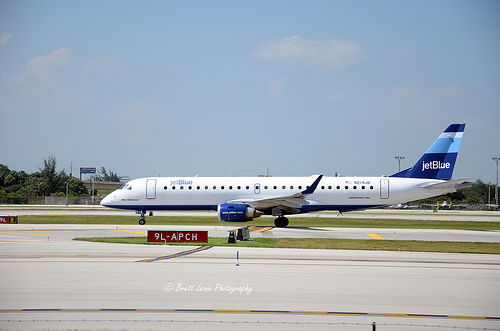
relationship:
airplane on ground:
[100, 123, 460, 221] [1, 229, 497, 328]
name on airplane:
[165, 181, 194, 186] [100, 123, 460, 221]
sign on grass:
[145, 230, 202, 243] [77, 232, 495, 258]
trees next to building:
[1, 165, 86, 203] [80, 175, 127, 194]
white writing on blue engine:
[223, 208, 245, 214] [218, 201, 256, 220]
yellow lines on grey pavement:
[354, 229, 392, 242] [117, 223, 495, 239]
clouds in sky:
[262, 32, 356, 60] [1, 3, 498, 177]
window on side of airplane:
[162, 185, 169, 190] [100, 123, 460, 221]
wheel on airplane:
[271, 217, 288, 226] [100, 123, 460, 221]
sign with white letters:
[145, 230, 202, 243] [153, 232, 203, 241]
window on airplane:
[370, 186, 376, 191] [100, 123, 460, 221]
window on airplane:
[361, 185, 367, 190] [100, 123, 460, 221]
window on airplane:
[351, 185, 356, 190] [100, 123, 460, 221]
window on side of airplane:
[344, 185, 349, 192] [100, 123, 460, 221]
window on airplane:
[336, 184, 341, 189] [100, 123, 460, 221]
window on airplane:
[320, 185, 328, 193] [100, 123, 460, 221]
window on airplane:
[328, 187, 332, 190] [100, 123, 460, 221]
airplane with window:
[100, 123, 460, 221] [299, 184, 305, 189]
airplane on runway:
[100, 123, 460, 221] [6, 216, 496, 264]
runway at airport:
[6, 216, 496, 264] [3, 4, 498, 329]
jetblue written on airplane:
[169, 178, 200, 186] [100, 123, 460, 221]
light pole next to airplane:
[484, 151, 500, 219] [100, 123, 460, 221]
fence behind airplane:
[28, 195, 106, 208] [100, 123, 460, 221]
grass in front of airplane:
[77, 232, 495, 258] [100, 123, 460, 221]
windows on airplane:
[160, 178, 391, 192] [100, 123, 460, 221]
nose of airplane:
[101, 186, 127, 213] [100, 123, 460, 221]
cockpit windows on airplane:
[118, 184, 134, 191] [100, 123, 460, 221]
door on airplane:
[145, 179, 158, 199] [100, 123, 460, 221]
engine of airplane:
[218, 201, 256, 220] [100, 123, 460, 221]